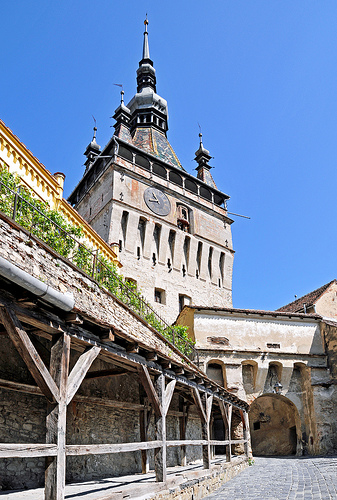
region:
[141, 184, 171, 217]
clock on old tower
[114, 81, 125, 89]
flag on top of tower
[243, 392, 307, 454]
entryway to building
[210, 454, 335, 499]
cobblestone pathway leading to building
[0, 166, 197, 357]
plants' leaves growing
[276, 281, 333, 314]
roof tiles on building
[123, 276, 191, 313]
windows in side of building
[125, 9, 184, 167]
steeple on top building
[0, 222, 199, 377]
shingles on roof of walkway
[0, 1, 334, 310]
bright blue sky with no clouds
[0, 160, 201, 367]
plants growing on balcony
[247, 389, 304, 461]
arched tunnel opening made of stone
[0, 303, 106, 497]
worn looking wood vertical support beam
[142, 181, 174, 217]
black clock on cement building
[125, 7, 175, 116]
concrete and metal decorative steeple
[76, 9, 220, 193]
rooftop with 3 small steeples and 1 large one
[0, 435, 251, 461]
worn looking wood banister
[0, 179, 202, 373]
metal railing on balcony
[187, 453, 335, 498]
light gray cobblestone driveway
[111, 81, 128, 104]
small flag on steeple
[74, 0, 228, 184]
metal spires on top of tower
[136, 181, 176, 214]
old clock face on tower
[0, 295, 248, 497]
sturdy support beams for a roofed walkway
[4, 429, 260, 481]
aged wood railing along walkway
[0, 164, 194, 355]
vegetation growing along iron railing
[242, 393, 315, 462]
arched entryway to structure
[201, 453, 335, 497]
stoned paved road leading to entrance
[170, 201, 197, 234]
a bowed window next to clock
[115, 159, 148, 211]
rust stain on front of tower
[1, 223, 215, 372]
old worn wooden roof shingles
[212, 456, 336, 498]
A sidewalk by the building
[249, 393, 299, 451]
A tunnel by the sidewalk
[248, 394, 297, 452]
The tunnel is an arch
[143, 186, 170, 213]
A clock on the building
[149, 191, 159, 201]
The hands on the clock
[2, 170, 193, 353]
Bushes on the building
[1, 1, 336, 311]
The sky above the building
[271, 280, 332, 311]
The roof of the building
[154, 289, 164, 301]
A window on the building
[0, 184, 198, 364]
A railing on the building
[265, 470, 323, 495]
The pavement is cobblestone.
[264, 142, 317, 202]
The sky is blue.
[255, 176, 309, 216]
The sky is clear.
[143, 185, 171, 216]
The clock is grey.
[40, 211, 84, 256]
The plants on the ledge are green.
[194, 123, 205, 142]
The spire on the right is made from metal.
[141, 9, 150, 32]
The spire on the top is made from metal.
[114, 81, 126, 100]
The spire on the left is made from metal.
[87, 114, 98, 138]
The spire in the back is made from metal.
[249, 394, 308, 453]
The building is light in color.